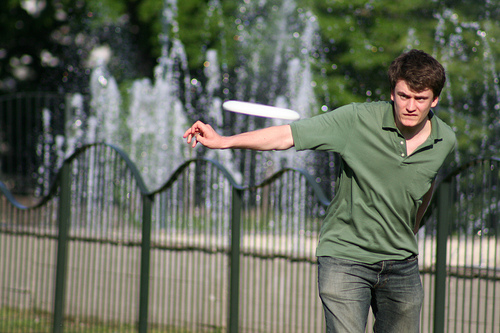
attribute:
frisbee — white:
[208, 93, 310, 125]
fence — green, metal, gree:
[2, 90, 494, 332]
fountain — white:
[25, 19, 472, 315]